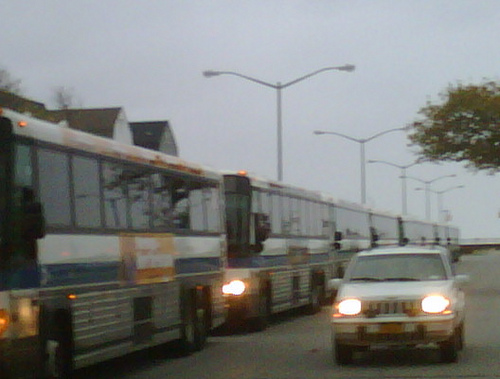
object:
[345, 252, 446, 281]
windshield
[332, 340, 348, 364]
wheel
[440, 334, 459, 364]
wheel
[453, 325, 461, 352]
wheel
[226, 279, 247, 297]
headlight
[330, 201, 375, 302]
bus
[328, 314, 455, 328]
bumper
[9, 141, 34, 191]
window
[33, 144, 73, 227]
window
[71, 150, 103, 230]
window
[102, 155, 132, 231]
window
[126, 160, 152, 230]
window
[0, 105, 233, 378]
bus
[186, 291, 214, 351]
wheel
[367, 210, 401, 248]
bus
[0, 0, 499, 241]
clouds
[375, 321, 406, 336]
license plate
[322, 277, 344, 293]
mirror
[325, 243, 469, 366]
car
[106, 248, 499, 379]
road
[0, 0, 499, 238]
sky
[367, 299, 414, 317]
grill